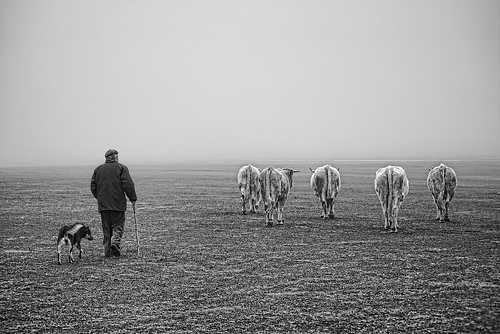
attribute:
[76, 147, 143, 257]
man — walking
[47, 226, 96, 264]
dog — walking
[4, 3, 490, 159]
sky — hazy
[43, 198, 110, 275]
dog — walking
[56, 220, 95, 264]
dog — black, white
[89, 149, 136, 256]
man — wearing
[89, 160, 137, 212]
jacket — dark colored, man's